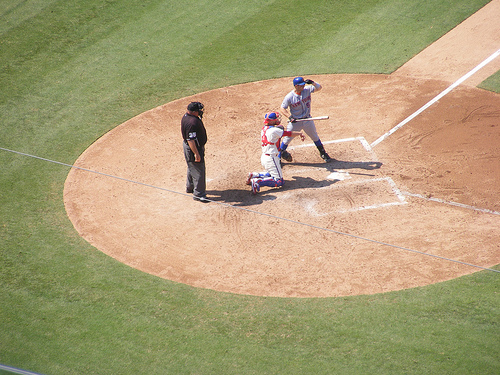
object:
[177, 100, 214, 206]
umpire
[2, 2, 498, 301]
game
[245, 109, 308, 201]
catcher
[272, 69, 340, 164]
batter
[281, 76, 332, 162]
player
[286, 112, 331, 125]
bat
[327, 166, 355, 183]
plate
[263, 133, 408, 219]
diamond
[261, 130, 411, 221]
box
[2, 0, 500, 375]
grass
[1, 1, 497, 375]
field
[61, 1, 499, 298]
dirt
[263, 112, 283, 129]
helmet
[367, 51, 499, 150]
baseline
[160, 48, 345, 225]
players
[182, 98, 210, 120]
helmet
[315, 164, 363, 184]
base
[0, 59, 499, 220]
markings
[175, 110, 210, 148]
shirt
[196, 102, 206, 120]
mask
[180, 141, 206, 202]
pants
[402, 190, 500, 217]
lines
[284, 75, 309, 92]
helmet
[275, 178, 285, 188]
pads